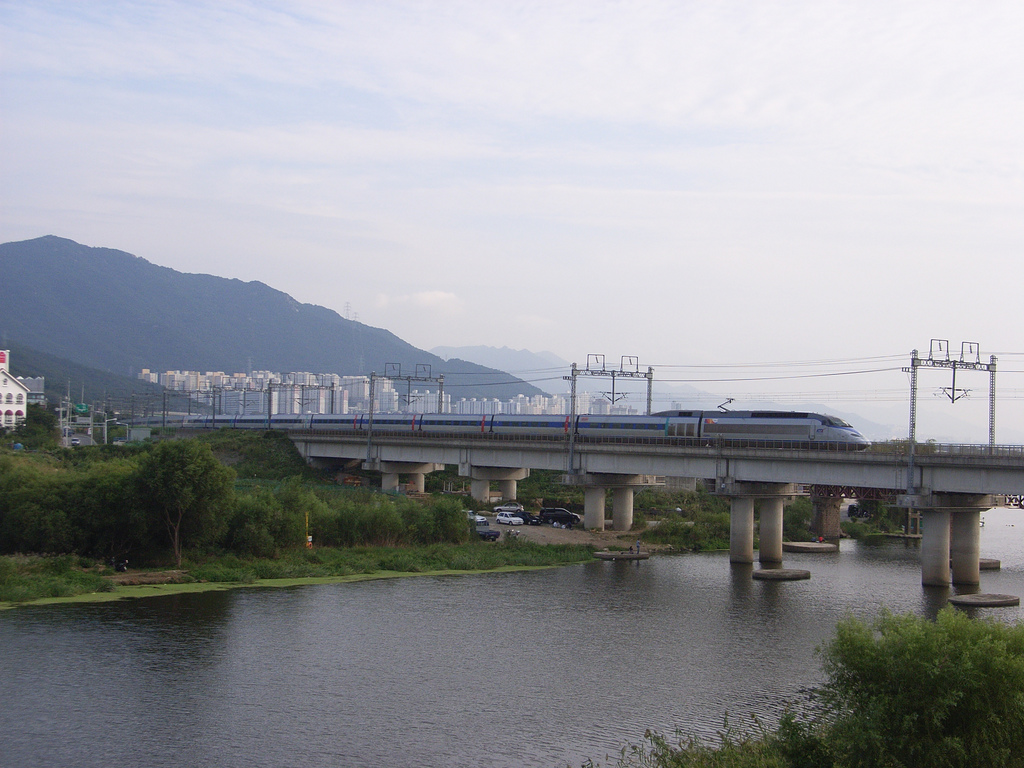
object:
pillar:
[382, 473, 399, 493]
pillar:
[408, 473, 424, 493]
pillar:
[502, 480, 517, 502]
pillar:
[584, 487, 604, 531]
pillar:
[585, 487, 634, 531]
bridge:
[123, 339, 1023, 588]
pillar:
[730, 498, 784, 563]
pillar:
[922, 510, 951, 588]